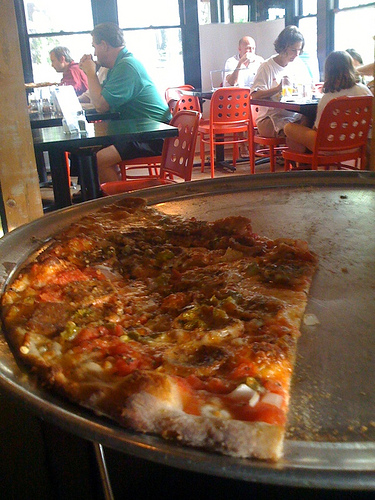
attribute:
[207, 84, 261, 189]
chair — red, wood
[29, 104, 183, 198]
table — black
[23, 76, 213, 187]
table — empty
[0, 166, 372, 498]
pizza — sliced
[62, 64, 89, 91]
shirt — red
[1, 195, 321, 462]
pizza — partially-eaten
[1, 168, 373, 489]
pan — metal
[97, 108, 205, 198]
chair — orange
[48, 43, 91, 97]
man — wearing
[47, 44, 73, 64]
hair — salt, pepper, short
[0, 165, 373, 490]
tray — silver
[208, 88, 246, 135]
chair — red, metal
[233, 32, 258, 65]
head — bald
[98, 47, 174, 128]
shirt — green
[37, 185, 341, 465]
pizza — couple, sliced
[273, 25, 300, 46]
hair — short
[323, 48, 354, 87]
hair — dark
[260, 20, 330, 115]
girl — little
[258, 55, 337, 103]
shirt — white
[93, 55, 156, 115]
shirt — green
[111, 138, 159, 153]
shorts — dark 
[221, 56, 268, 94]
shirt — white